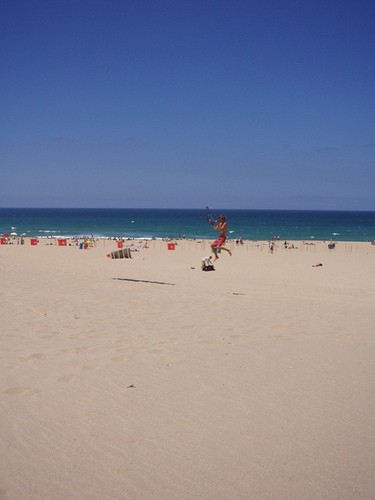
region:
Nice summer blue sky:
[125, 111, 190, 143]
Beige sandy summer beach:
[47, 285, 88, 311]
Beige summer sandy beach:
[184, 309, 241, 337]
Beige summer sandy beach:
[264, 311, 320, 336]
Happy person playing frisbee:
[205, 204, 233, 262]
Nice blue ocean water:
[147, 212, 188, 222]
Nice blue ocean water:
[251, 215, 305, 226]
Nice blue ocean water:
[16, 212, 46, 224]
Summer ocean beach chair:
[164, 241, 176, 251]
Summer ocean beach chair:
[56, 237, 67, 245]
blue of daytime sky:
[2, 2, 372, 205]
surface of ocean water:
[0, 208, 373, 234]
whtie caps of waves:
[60, 231, 159, 239]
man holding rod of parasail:
[207, 213, 232, 262]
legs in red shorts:
[211, 237, 233, 260]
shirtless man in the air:
[209, 215, 231, 261]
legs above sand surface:
[212, 247, 243, 275]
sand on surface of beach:
[0, 245, 372, 499]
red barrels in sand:
[6, 236, 178, 252]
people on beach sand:
[67, 230, 201, 251]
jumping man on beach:
[203, 209, 234, 261]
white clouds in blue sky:
[4, 63, 62, 102]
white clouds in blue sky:
[30, 114, 79, 155]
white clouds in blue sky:
[89, 82, 120, 138]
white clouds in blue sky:
[162, 90, 212, 136]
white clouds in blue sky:
[225, 111, 264, 161]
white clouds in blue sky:
[245, 109, 306, 174]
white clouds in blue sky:
[286, 137, 328, 191]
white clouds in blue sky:
[231, 66, 301, 119]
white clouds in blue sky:
[148, 77, 197, 138]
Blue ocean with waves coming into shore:
[3, 202, 374, 245]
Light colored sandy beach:
[6, 236, 367, 496]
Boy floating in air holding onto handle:
[198, 203, 237, 260]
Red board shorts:
[207, 228, 231, 253]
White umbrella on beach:
[8, 226, 17, 238]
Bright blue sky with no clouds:
[5, 0, 370, 212]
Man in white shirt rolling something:
[197, 252, 215, 275]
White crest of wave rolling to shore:
[31, 223, 64, 238]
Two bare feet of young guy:
[209, 247, 236, 265]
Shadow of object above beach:
[109, 269, 178, 298]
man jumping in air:
[203, 209, 236, 260]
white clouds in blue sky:
[11, 10, 68, 68]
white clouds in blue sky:
[69, 56, 125, 107]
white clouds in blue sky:
[148, 100, 191, 146]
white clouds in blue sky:
[48, 131, 121, 179]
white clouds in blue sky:
[233, 131, 278, 186]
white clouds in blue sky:
[221, 42, 269, 84]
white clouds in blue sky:
[146, 53, 210, 115]